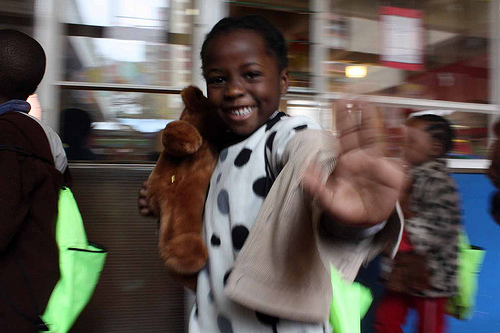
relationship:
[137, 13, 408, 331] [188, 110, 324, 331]
child wearing polka dots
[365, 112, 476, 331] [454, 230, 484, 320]
young child wearing backpack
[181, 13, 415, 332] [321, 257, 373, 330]
child wearing backpack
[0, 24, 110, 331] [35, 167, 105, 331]
young child wearing backpack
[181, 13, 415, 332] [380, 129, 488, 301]
child in coat